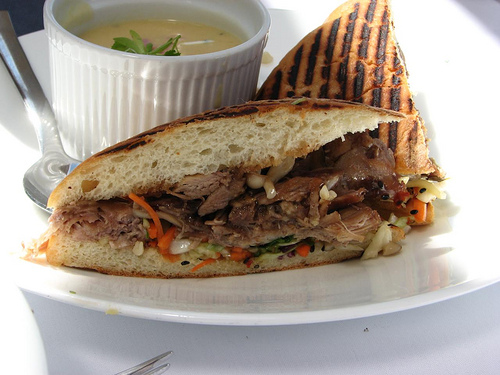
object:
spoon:
[0, 9, 82, 211]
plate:
[3, 1, 483, 327]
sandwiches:
[21, 1, 445, 280]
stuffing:
[53, 124, 392, 236]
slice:
[156, 226, 178, 255]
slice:
[221, 240, 253, 268]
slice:
[295, 239, 311, 260]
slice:
[401, 190, 432, 223]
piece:
[127, 190, 165, 240]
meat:
[52, 137, 399, 247]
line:
[316, 14, 341, 97]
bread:
[253, 0, 434, 177]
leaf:
[106, 22, 180, 55]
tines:
[120, 349, 177, 373]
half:
[32, 96, 420, 287]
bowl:
[37, 0, 272, 162]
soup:
[89, 12, 219, 46]